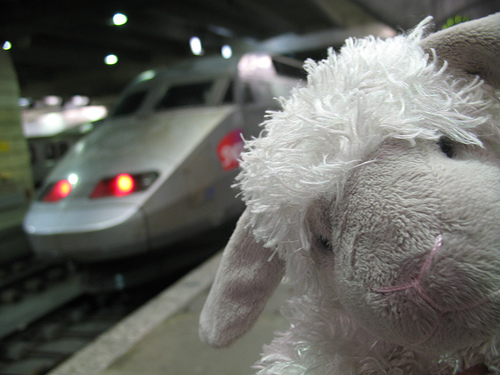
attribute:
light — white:
[0, 36, 18, 54]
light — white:
[102, 50, 119, 69]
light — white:
[110, 11, 134, 31]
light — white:
[184, 33, 205, 60]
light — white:
[216, 41, 235, 60]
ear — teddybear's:
[192, 190, 292, 347]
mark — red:
[220, 127, 250, 175]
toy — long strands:
[191, 22, 476, 359]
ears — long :
[193, 188, 292, 345]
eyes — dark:
[298, 228, 351, 268]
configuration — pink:
[366, 233, 461, 313]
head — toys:
[196, 30, 481, 355]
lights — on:
[42, 162, 146, 209]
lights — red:
[48, 170, 134, 201]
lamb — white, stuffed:
[199, 30, 470, 362]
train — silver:
[1, 89, 266, 272]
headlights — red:
[35, 171, 138, 197]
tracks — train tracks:
[0, 285, 97, 371]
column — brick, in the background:
[0, 33, 35, 215]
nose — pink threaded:
[375, 228, 447, 292]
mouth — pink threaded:
[401, 289, 483, 367]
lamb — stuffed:
[179, 10, 481, 372]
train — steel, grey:
[11, 44, 383, 311]